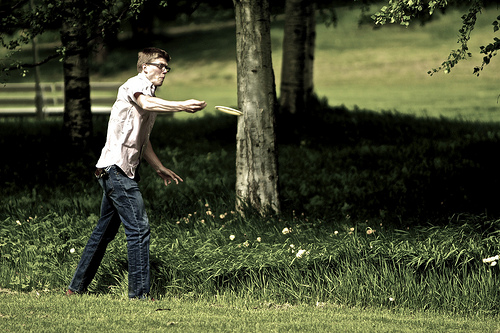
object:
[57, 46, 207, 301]
man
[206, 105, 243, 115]
frisbee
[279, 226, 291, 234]
flowers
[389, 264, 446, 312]
grass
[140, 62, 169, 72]
glasses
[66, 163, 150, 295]
blue jeans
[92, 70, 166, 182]
shirt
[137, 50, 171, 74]
brown hair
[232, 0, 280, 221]
trunk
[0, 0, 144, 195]
tree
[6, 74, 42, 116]
fence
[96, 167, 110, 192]
pocket flap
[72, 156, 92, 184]
back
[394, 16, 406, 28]
leaves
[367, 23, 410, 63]
sunlight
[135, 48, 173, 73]
hair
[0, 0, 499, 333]
park